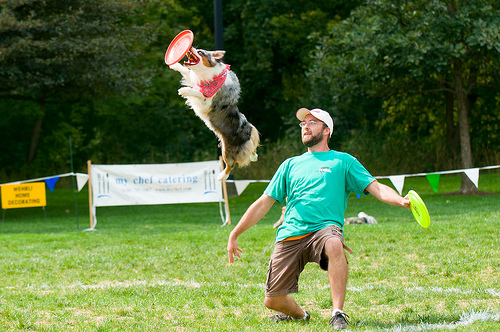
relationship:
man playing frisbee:
[226, 108, 410, 332] [398, 192, 439, 232]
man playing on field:
[226, 108, 410, 332] [3, 150, 496, 330]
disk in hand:
[407, 189, 430, 228] [391, 187, 401, 209]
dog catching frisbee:
[165, 46, 260, 181] [164, 28, 194, 65]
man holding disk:
[226, 108, 410, 332] [407, 189, 430, 228]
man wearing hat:
[226, 108, 410, 332] [289, 98, 349, 140]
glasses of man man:
[296, 118, 324, 125] [226, 108, 410, 332]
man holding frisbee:
[226, 108, 410, 332] [405, 187, 432, 228]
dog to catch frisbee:
[165, 46, 260, 181] [161, 25, 193, 65]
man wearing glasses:
[226, 108, 410, 332] [290, 112, 327, 129]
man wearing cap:
[226, 108, 410, 332] [295, 101, 332, 135]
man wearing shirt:
[226, 108, 410, 332] [262, 148, 372, 243]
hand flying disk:
[397, 190, 412, 209] [405, 189, 432, 229]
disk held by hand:
[405, 189, 432, 229] [397, 190, 412, 209]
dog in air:
[165, 46, 260, 181] [8, 19, 483, 105]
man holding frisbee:
[234, 99, 440, 326] [394, 183, 429, 220]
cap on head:
[296, 108, 334, 137] [299, 119, 326, 142]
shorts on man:
[263, 230, 345, 297] [239, 110, 367, 325]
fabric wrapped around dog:
[198, 65, 233, 96] [165, 46, 260, 181]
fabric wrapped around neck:
[198, 65, 233, 96] [185, 65, 226, 89]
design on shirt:
[310, 163, 331, 173] [262, 148, 372, 243]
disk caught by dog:
[407, 189, 430, 228] [169, 32, 264, 184]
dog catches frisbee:
[165, 46, 260, 181] [410, 183, 431, 233]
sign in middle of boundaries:
[3, 176, 48, 210] [61, 156, 237, 221]